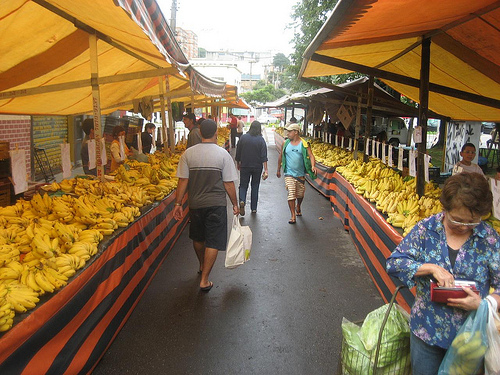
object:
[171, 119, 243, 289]
man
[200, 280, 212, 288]
feet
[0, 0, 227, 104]
awnings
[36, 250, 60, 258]
bananas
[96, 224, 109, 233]
bananas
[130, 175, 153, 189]
bananas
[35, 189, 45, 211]
bananas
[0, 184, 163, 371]
table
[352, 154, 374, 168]
bananas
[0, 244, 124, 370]
tablecloth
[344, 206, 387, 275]
cover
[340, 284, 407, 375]
packages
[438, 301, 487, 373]
bag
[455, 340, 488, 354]
bananas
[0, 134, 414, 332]
large number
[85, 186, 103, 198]
bananas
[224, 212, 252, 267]
bag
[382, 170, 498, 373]
woman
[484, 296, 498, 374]
multiple bags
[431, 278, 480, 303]
her wallet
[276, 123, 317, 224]
man is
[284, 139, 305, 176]
blue shirt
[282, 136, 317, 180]
green jacket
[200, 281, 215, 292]
sandals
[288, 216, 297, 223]
pedestrians feet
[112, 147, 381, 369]
cement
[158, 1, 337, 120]
in the distance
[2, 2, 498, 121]
yellow and orange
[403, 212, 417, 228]
bunch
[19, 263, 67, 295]
bunch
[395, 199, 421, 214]
bunch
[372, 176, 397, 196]
bananas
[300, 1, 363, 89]
trees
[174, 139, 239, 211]
gray shirt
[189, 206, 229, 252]
dark pants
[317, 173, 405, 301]
black and orange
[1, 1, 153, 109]
canopy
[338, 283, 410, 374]
cart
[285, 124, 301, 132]
ballcap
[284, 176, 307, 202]
striped shorts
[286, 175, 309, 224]
shorts walking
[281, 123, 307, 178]
hat and blue shirt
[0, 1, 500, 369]
produce stand